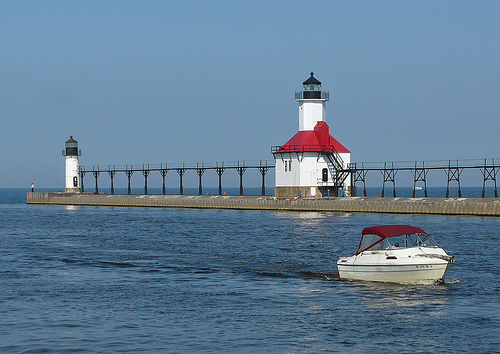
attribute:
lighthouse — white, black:
[59, 132, 88, 199]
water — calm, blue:
[64, 224, 499, 347]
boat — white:
[332, 211, 456, 304]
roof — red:
[274, 125, 350, 163]